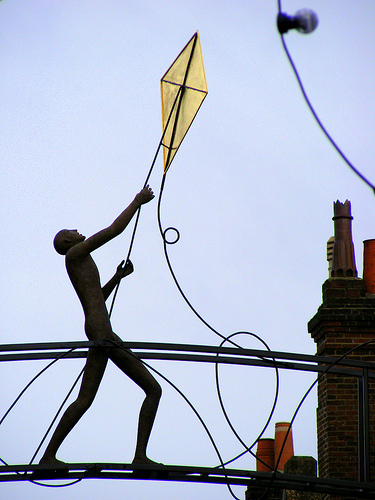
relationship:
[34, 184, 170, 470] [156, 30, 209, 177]
statue with kite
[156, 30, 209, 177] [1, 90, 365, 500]
kite has string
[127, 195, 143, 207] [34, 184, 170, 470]
right wrist of statue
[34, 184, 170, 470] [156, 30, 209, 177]
statue flying kite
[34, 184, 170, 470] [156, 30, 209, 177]
statue of kite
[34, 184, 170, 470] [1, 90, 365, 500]
statue holding string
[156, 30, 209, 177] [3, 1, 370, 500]
kite in sky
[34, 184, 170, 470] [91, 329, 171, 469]
statue has legs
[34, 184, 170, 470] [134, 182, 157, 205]
statue has hand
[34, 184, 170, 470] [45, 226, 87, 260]
statue has head